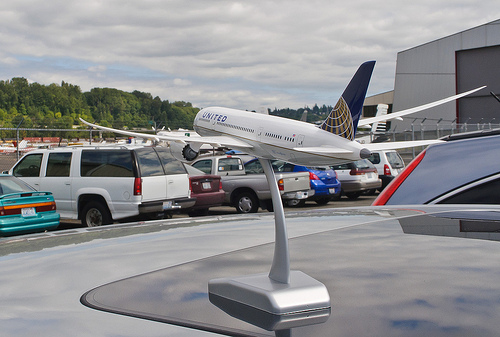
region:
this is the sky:
[163, 2, 312, 98]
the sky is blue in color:
[96, 63, 153, 75]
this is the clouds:
[199, 30, 305, 63]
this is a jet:
[198, 105, 369, 168]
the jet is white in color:
[253, 120, 285, 135]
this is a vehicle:
[58, 140, 179, 210]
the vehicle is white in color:
[102, 179, 136, 200]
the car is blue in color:
[312, 174, 331, 184]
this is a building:
[403, 14, 478, 103]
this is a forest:
[97, 93, 154, 121]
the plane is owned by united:
[178, 65, 384, 181]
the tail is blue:
[327, 62, 369, 143]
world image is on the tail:
[330, 96, 366, 136]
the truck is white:
[21, 145, 191, 218]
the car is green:
[5, 165, 67, 237]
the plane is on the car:
[75, 85, 491, 197]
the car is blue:
[306, 166, 341, 198]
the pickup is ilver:
[205, 156, 315, 208]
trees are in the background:
[15, 74, 180, 131]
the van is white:
[345, 163, 385, 189]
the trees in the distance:
[0, 75, 332, 135]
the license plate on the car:
[20, 206, 36, 216]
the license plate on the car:
[161, 200, 173, 210]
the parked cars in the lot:
[0, 126, 496, 332]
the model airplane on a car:
[77, 60, 485, 312]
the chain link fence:
[0, 113, 497, 173]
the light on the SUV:
[132, 175, 141, 197]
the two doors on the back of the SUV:
[132, 145, 190, 201]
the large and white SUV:
[3, 142, 197, 226]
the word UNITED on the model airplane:
[200, 110, 227, 122]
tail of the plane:
[316, 55, 396, 142]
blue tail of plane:
[312, 62, 399, 134]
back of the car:
[120, 133, 196, 217]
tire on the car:
[75, 195, 117, 238]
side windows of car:
[10, 141, 70, 182]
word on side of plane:
[196, 105, 237, 128]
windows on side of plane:
[197, 113, 303, 156]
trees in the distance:
[8, 69, 127, 128]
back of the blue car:
[304, 164, 351, 201]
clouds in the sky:
[136, 17, 267, 92]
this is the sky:
[68, 60, 92, 67]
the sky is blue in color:
[49, 60, 75, 70]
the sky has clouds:
[213, 11, 312, 67]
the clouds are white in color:
[235, 10, 336, 71]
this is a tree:
[11, 85, 39, 105]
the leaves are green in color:
[9, 84, 121, 114]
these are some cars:
[13, 150, 283, 211]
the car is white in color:
[149, 180, 177, 197]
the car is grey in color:
[233, 173, 250, 184]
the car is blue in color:
[321, 173, 328, 179]